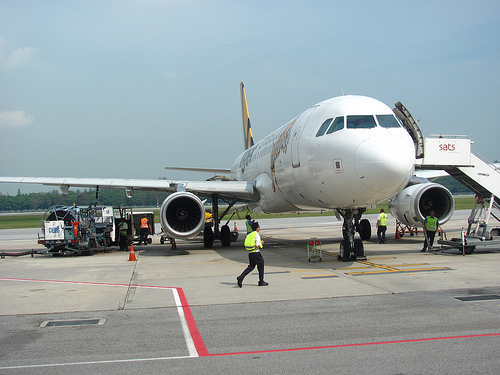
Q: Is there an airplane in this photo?
A: Yes, there is an airplane.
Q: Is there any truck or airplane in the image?
A: Yes, there is an airplane.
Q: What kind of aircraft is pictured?
A: The aircraft is an airplane.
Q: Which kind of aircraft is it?
A: The aircraft is an airplane.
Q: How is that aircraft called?
A: This is an airplane.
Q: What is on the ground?
A: The airplane is on the ground.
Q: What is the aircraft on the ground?
A: The aircraft is an airplane.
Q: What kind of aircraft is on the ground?
A: The aircraft is an airplane.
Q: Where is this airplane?
A: The airplane is on the ground.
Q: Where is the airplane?
A: The airplane is on the ground.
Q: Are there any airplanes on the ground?
A: Yes, there is an airplane on the ground.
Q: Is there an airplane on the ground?
A: Yes, there is an airplane on the ground.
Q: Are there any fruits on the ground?
A: No, there is an airplane on the ground.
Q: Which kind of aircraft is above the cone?
A: The aircraft is an airplane.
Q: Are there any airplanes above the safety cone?
A: Yes, there is an airplane above the safety cone.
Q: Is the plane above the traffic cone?
A: Yes, the plane is above the traffic cone.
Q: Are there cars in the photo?
A: No, there are no cars.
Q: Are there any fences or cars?
A: No, there are no cars or fences.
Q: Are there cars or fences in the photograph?
A: No, there are no cars or fences.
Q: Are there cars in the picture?
A: No, there are no cars.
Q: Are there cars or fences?
A: No, there are no cars or fences.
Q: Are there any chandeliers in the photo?
A: No, there are no chandeliers.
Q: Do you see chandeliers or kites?
A: No, there are no chandeliers or kites.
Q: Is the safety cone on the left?
A: Yes, the safety cone is on the left of the image.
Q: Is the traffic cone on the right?
A: No, the traffic cone is on the left of the image.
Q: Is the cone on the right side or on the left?
A: The cone is on the left of the image.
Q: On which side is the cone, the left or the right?
A: The cone is on the left of the image.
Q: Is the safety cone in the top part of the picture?
A: No, the safety cone is in the bottom of the image.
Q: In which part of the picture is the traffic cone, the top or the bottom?
A: The traffic cone is in the bottom of the image.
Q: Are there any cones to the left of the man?
A: Yes, there is a cone to the left of the man.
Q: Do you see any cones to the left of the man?
A: Yes, there is a cone to the left of the man.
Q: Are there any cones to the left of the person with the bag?
A: Yes, there is a cone to the left of the man.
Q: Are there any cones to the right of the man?
A: No, the cone is to the left of the man.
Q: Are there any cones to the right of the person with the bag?
A: No, the cone is to the left of the man.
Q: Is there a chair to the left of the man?
A: No, there is a cone to the left of the man.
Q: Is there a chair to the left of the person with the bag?
A: No, there is a cone to the left of the man.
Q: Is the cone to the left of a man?
A: Yes, the cone is to the left of a man.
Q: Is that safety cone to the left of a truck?
A: No, the safety cone is to the left of a man.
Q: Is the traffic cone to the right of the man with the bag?
A: No, the traffic cone is to the left of the man.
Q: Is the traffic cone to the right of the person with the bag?
A: No, the traffic cone is to the left of the man.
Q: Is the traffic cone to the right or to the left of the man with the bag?
A: The traffic cone is to the left of the man.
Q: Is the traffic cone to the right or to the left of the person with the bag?
A: The traffic cone is to the left of the man.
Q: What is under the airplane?
A: The traffic cone is under the airplane.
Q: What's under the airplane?
A: The traffic cone is under the airplane.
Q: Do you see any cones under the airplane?
A: Yes, there is a cone under the airplane.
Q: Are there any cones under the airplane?
A: Yes, there is a cone under the airplane.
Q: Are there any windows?
A: Yes, there is a window.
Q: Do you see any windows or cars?
A: Yes, there is a window.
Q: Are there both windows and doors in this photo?
A: No, there is a window but no doors.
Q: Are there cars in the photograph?
A: No, there are no cars.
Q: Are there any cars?
A: No, there are no cars.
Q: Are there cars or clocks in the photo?
A: No, there are no cars or clocks.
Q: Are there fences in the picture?
A: No, there are no fences.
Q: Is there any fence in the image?
A: No, there are no fences.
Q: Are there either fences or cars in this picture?
A: No, there are no fences or cars.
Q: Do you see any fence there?
A: No, there are no fences.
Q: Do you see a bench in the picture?
A: No, there are no benches.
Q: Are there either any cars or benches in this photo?
A: No, there are no benches or cars.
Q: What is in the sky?
A: The clouds are in the sky.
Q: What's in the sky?
A: The clouds are in the sky.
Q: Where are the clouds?
A: The clouds are in the sky.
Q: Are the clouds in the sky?
A: Yes, the clouds are in the sky.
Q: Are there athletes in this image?
A: No, there are no athletes.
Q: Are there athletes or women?
A: No, there are no athletes or women.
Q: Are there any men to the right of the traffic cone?
A: Yes, there is a man to the right of the traffic cone.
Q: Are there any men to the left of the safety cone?
A: No, the man is to the right of the safety cone.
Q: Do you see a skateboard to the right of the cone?
A: No, there is a man to the right of the cone.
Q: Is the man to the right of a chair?
A: No, the man is to the right of the traffic cone.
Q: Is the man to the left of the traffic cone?
A: No, the man is to the right of the traffic cone.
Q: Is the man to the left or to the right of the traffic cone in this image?
A: The man is to the right of the traffic cone.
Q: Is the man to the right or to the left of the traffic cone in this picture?
A: The man is to the right of the traffic cone.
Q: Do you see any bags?
A: Yes, there is a bag.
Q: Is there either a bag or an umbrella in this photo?
A: Yes, there is a bag.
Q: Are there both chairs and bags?
A: No, there is a bag but no chairs.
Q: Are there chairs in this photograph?
A: No, there are no chairs.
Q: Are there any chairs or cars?
A: No, there are no chairs or cars.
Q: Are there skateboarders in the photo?
A: No, there are no skateboarders.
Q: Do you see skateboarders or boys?
A: No, there are no skateboarders or boys.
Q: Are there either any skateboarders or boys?
A: No, there are no skateboarders or boys.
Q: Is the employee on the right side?
A: Yes, the employee is on the right of the image.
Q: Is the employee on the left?
A: No, the employee is on the right of the image.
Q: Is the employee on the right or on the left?
A: The employee is on the right of the image.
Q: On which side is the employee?
A: The employee is on the right of the image.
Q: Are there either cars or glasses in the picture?
A: No, there are no cars or glasses.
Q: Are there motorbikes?
A: No, there are no motorbikes.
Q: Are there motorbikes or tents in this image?
A: No, there are no motorbikes or tents.